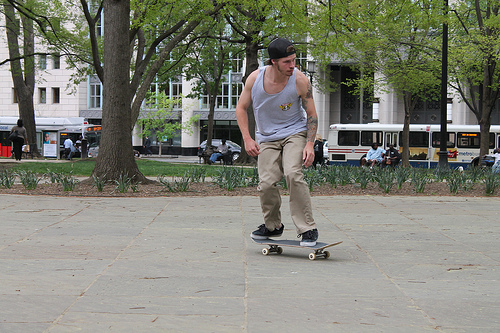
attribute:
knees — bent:
[257, 163, 312, 190]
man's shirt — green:
[318, 116, 491, 163]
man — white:
[224, 36, 361, 245]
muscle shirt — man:
[249, 65, 307, 138]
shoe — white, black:
[295, 224, 320, 248]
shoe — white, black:
[249, 219, 291, 242]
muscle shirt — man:
[247, 67, 307, 134]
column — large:
[167, 66, 203, 143]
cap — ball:
[267, 35, 299, 55]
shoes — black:
[251, 223, 322, 247]